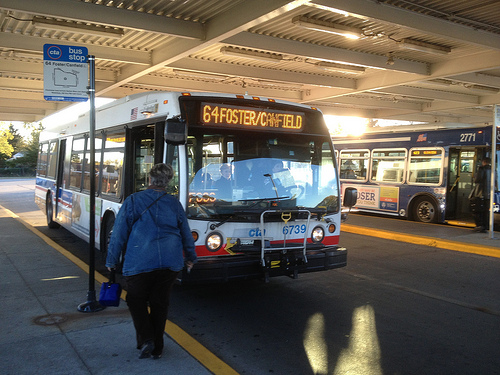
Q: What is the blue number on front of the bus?
A: 6739.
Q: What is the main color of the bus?
A: White.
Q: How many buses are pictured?
A: 2.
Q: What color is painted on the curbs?
A: Yellow.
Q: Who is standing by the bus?
A: The woman.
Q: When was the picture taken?
A: Daytime.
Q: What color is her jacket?
A: Blue.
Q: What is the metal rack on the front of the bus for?
A: Holding bikes.